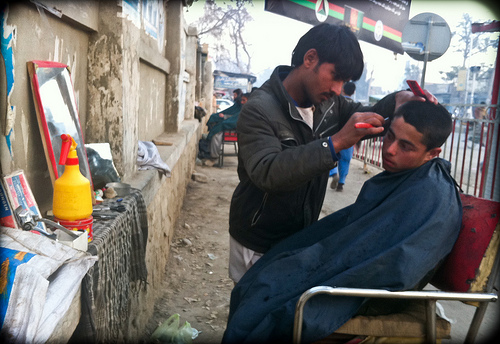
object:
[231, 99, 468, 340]
boy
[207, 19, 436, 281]
barber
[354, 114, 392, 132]
item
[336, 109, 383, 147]
hand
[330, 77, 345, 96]
nose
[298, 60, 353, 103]
face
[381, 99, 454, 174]
head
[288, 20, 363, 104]
head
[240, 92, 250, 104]
head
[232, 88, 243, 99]
head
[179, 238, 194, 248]
rocks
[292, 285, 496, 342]
arm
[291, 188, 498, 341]
chair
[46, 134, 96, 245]
bottle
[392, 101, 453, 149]
hair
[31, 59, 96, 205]
mirror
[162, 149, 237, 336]
ground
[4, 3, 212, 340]
wall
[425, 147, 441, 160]
ear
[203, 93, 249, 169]
kid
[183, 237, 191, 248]
rock